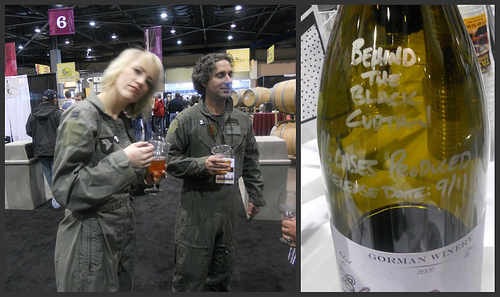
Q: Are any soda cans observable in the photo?
A: No, there are no soda cans.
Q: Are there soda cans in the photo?
A: No, there are no soda cans.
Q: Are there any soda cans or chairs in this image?
A: No, there are no soda cans or chairs.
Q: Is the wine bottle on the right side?
A: Yes, the wine bottle is on the right of the image.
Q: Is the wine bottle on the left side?
A: No, the wine bottle is on the right of the image.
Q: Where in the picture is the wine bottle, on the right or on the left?
A: The wine bottle is on the right of the image.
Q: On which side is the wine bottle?
A: The wine bottle is on the right of the image.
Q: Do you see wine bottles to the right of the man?
A: Yes, there is a wine bottle to the right of the man.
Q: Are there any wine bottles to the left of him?
A: No, the wine bottle is to the right of the man.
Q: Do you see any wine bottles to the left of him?
A: No, the wine bottle is to the right of the man.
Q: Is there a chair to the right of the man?
A: No, there is a wine bottle to the right of the man.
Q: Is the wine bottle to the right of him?
A: Yes, the wine bottle is to the right of the man.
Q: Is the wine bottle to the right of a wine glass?
A: No, the wine bottle is to the right of the man.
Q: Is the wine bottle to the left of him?
A: No, the wine bottle is to the right of the man.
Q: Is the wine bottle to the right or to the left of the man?
A: The wine bottle is to the right of the man.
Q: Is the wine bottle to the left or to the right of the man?
A: The wine bottle is to the right of the man.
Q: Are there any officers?
A: No, there are no officers.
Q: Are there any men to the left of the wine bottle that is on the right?
A: Yes, there is a man to the left of the wine bottle.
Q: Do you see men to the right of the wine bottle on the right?
A: No, the man is to the left of the wine bottle.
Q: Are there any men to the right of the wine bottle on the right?
A: No, the man is to the left of the wine bottle.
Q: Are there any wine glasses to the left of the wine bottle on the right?
A: No, there is a man to the left of the wine bottle.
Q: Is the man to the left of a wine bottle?
A: Yes, the man is to the left of a wine bottle.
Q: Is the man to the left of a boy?
A: No, the man is to the left of a wine bottle.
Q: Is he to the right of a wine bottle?
A: No, the man is to the left of a wine bottle.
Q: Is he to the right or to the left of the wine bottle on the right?
A: The man is to the left of the wine bottle.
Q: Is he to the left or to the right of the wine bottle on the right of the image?
A: The man is to the left of the wine bottle.